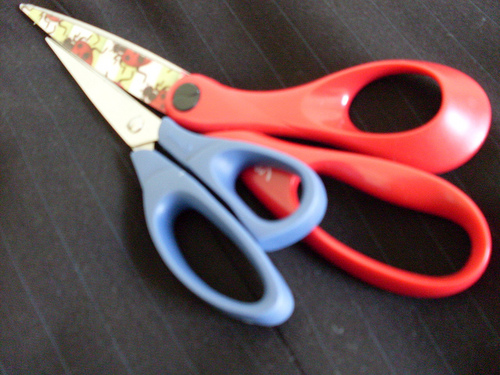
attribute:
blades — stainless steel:
[16, 4, 168, 143]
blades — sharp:
[20, 2, 189, 151]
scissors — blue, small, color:
[84, 84, 318, 282]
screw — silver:
[129, 119, 144, 136]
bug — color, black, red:
[53, 32, 102, 72]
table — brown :
[4, 98, 164, 305]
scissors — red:
[16, 2, 492, 297]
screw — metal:
[146, 88, 219, 114]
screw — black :
[160, 72, 217, 130]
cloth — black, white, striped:
[2, 3, 496, 373]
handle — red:
[190, 57, 490, 299]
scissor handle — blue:
[192, 125, 497, 300]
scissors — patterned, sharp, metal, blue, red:
[19, 0, 491, 327]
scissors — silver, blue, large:
[39, 28, 331, 334]